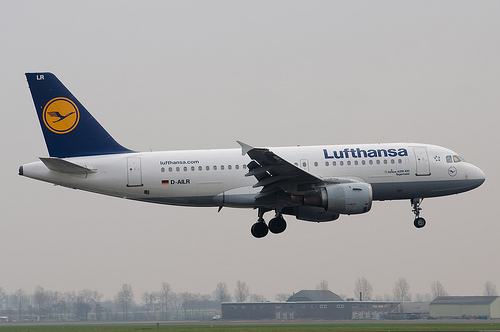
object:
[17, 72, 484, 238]
plane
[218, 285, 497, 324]
building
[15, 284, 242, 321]
trees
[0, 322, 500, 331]
grass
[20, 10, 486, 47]
sky